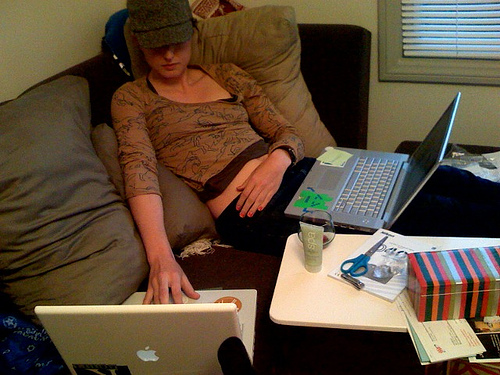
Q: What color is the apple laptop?
A: White.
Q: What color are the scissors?
A: Blue.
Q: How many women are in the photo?
A: One.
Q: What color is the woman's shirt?
A: Brown.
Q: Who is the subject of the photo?
A: The woman.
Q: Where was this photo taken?
A: The living room.